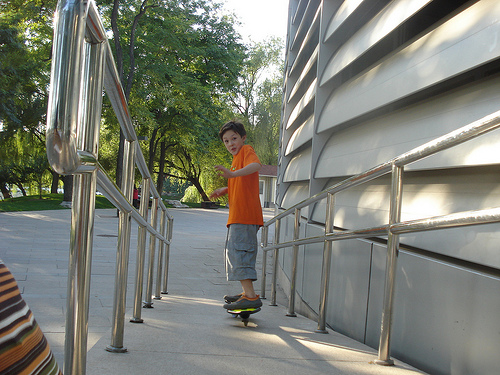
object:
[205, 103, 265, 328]
boy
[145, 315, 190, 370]
ramp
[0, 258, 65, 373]
sleeve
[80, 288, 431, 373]
sidewalk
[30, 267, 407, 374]
paved area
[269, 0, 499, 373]
building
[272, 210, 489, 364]
wall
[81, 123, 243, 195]
bad object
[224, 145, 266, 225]
shirt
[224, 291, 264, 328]
skateboard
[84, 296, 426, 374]
walkway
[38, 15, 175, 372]
railings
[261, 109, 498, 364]
railings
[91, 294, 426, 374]
ramp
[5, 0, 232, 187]
trees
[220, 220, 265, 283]
shorts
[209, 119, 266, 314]
kid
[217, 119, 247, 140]
dark hair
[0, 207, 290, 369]
patio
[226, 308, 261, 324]
board